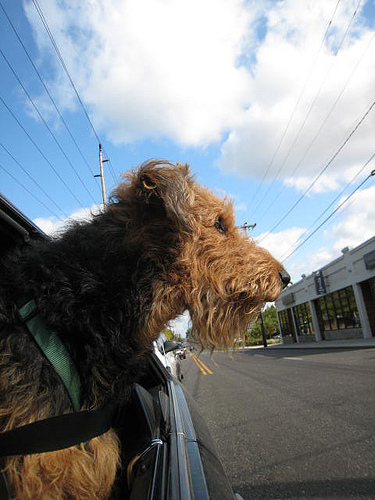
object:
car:
[0, 196, 245, 499]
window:
[2, 201, 179, 499]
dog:
[0, 156, 292, 496]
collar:
[13, 293, 87, 412]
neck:
[44, 211, 163, 375]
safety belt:
[0, 395, 117, 454]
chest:
[3, 388, 121, 499]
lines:
[187, 347, 213, 378]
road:
[173, 342, 374, 498]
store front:
[276, 245, 374, 349]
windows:
[324, 320, 330, 330]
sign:
[280, 291, 295, 306]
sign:
[315, 271, 327, 295]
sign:
[361, 250, 374, 270]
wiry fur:
[191, 310, 255, 362]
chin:
[197, 286, 264, 318]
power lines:
[1, 1, 108, 213]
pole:
[93, 143, 111, 211]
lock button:
[136, 459, 149, 476]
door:
[133, 378, 219, 499]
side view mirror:
[163, 338, 178, 354]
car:
[154, 331, 187, 379]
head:
[117, 158, 292, 343]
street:
[173, 343, 374, 500]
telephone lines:
[274, 94, 293, 154]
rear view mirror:
[162, 338, 178, 354]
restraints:
[4, 288, 110, 457]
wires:
[44, 0, 77, 91]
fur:
[80, 312, 153, 392]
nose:
[277, 268, 292, 287]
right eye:
[213, 213, 229, 234]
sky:
[0, 1, 375, 158]